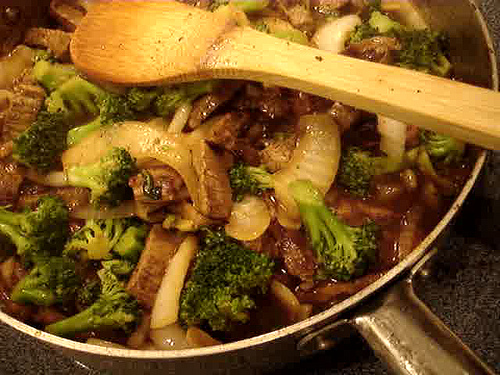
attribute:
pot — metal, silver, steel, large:
[1, 0, 492, 374]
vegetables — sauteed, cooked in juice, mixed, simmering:
[1, 0, 468, 334]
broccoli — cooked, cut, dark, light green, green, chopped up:
[10, 114, 66, 173]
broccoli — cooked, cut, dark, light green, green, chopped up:
[66, 149, 136, 204]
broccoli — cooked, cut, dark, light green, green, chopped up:
[288, 179, 378, 283]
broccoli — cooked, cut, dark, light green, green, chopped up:
[1, 198, 68, 265]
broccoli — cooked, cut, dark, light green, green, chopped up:
[181, 228, 275, 334]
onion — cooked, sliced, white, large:
[60, 120, 231, 219]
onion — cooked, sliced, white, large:
[272, 114, 343, 228]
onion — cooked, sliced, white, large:
[311, 15, 361, 54]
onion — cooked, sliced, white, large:
[150, 234, 200, 330]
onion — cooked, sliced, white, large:
[377, 114, 407, 163]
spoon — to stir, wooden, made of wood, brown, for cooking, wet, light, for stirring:
[71, 3, 500, 154]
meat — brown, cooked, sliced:
[2, 78, 46, 147]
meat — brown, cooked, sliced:
[208, 111, 251, 150]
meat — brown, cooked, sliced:
[275, 227, 314, 279]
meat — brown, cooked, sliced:
[23, 26, 71, 57]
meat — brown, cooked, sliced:
[126, 223, 183, 310]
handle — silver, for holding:
[296, 248, 497, 375]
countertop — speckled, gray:
[2, 19, 499, 375]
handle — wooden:
[250, 28, 500, 154]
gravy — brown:
[329, 177, 455, 265]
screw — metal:
[315, 336, 337, 354]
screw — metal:
[417, 264, 435, 285]